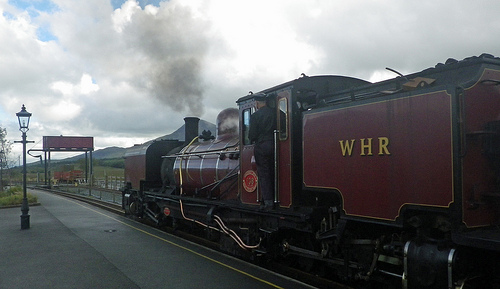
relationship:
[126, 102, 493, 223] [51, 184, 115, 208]
train on tracks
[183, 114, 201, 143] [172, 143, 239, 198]
stack on engine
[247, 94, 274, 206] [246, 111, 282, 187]
engineer wearing black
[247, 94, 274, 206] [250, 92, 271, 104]
engineer wearing cap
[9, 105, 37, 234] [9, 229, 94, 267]
lamppost on pavement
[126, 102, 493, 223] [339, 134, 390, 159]
train has initials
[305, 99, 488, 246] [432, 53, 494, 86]
car with coal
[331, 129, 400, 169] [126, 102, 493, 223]
letters on train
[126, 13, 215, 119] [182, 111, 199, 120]
exaust comes out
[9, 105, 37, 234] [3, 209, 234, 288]
lamppost on platform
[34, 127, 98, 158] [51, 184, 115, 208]
sign above tracks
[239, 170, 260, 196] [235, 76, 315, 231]
emblem on car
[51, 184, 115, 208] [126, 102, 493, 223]
tracks for train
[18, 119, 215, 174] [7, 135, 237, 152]
mountains in distance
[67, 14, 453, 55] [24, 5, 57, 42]
clouds in sky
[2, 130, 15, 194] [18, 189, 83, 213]
tree by sidewalk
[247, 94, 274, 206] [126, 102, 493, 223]
engineer in train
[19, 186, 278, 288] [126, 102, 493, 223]
line by train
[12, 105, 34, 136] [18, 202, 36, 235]
light with base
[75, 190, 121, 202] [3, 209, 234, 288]
railings by platform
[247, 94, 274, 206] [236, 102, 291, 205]
engineer in door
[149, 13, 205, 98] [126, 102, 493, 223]
smoke from train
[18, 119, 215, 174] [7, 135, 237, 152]
mountains in background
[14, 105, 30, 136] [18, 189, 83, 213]
light on sidewalk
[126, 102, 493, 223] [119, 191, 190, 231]
train has stopped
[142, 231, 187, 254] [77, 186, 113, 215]
line near track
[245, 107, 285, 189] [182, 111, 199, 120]
conductor looking out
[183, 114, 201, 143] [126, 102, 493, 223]
stack on train